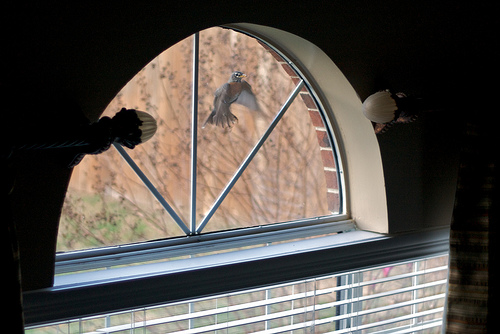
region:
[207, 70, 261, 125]
bird in midflight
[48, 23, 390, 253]
bird outside of an arched window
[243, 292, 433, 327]
white mini blinds covering a window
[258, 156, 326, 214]
trees outside the window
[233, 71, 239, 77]
bird's black eye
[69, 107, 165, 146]
end of a curtain rod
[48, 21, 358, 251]
window in the shape of a half-circle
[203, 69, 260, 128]
bird flapping its wings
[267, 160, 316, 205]
daylight outside of the window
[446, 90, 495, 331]
curtain panel next to the window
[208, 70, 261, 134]
bird outside window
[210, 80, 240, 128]
grey colored bird wing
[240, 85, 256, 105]
grey colored bird wing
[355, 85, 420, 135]
white colored wall light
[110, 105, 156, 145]
white colored wall light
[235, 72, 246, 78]
orange colored bird beak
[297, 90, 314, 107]
red colored building brick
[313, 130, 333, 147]
red colored building brick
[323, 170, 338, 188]
red colored building brick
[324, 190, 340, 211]
red colored building brick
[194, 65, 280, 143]
a bird looking in a window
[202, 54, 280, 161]
a bird flying near a window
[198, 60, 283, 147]
a bird at a window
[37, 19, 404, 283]
An arched window with a bird outside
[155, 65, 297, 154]
A bird outside a window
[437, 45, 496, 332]
A curtain hanging near a window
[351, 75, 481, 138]
A finial on a curtain rod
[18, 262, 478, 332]
Blinds on a window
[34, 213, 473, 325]
White trim around a window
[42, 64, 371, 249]
A tree outside the window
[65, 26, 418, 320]
Small windown with 4 panes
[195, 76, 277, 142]
Bird flying towards window on other side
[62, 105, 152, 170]
Silhouette of round object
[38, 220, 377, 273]
White window sill under window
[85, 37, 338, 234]
Branches and leaves through window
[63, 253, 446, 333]
Rectangle window under sil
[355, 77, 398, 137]
White cone shaped object on right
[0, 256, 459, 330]
Blinds on long window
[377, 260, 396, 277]
Small flower through window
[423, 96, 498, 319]
Dark curtain on right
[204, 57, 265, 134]
the bird is outside the window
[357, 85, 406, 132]
the light is off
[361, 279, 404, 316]
the blinds are open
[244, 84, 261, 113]
the bird has a wing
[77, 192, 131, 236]
the branches are brown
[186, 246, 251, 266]
the widow seal is white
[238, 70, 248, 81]
the beak is yellow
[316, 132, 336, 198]
the bricks are red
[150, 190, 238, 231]
the bars are white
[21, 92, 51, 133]
the wall is dark